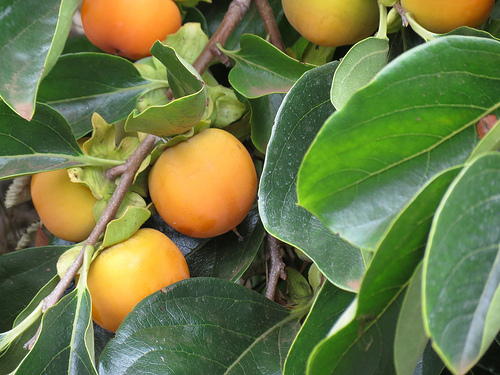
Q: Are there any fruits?
A: Yes, there is a fruit.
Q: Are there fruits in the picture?
A: Yes, there is a fruit.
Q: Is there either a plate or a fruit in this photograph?
A: Yes, there is a fruit.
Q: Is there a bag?
A: No, there are no bags.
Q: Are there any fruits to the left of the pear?
A: Yes, there is a fruit to the left of the pear.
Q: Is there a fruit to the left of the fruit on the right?
A: Yes, there is a fruit to the left of the pear.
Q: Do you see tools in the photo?
A: No, there are no tools.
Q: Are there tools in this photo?
A: No, there are no tools.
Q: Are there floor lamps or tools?
A: No, there are no tools or floor lamps.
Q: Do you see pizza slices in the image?
A: No, there are no pizza slices.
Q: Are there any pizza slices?
A: No, there are no pizza slices.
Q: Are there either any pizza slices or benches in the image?
A: No, there are no pizza slices or benches.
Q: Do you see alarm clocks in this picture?
A: No, there are no alarm clocks.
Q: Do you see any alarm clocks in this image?
A: No, there are no alarm clocks.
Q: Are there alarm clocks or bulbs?
A: No, there are no alarm clocks or bulbs.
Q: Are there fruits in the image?
A: Yes, there is a fruit.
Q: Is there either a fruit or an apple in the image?
A: Yes, there is a fruit.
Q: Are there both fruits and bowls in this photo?
A: No, there is a fruit but no bowls.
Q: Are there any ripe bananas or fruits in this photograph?
A: Yes, there is a ripe fruit.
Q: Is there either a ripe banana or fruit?
A: Yes, there is a ripe fruit.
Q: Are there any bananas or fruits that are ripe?
A: Yes, the fruit is ripe.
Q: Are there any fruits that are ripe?
A: Yes, there is a ripe fruit.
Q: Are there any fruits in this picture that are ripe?
A: Yes, there is a fruit that is ripe.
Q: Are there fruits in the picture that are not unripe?
A: Yes, there is an ripe fruit.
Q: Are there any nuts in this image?
A: No, there are no nuts.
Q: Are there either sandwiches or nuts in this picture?
A: No, there are no nuts or sandwiches.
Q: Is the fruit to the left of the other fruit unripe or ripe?
A: The fruit is ripe.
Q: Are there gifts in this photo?
A: No, there are no gifts.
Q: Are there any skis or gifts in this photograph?
A: No, there are no gifts or skis.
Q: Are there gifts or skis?
A: No, there are no gifts or skis.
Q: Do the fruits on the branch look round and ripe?
A: Yes, the fruits are round and ripe.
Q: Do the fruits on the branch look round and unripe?
A: No, the fruits are round but ripe.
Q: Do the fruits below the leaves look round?
A: Yes, the fruits are round.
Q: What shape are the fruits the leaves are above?
A: The fruits are round.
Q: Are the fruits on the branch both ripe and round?
A: Yes, the fruits are ripe and round.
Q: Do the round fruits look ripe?
A: Yes, the fruits are ripe.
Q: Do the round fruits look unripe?
A: No, the fruits are ripe.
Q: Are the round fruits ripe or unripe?
A: The fruits are ripe.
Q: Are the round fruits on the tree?
A: Yes, the fruits are on the tree.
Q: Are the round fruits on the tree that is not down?
A: Yes, the fruits are on the tree.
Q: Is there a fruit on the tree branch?
A: Yes, there are fruits on the branch.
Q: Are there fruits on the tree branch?
A: Yes, there are fruits on the branch.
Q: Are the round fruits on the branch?
A: Yes, the fruits are on the branch.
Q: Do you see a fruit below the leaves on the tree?
A: Yes, there are fruits below the leaves.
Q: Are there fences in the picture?
A: No, there are no fences.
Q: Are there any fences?
A: No, there are no fences.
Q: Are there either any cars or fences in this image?
A: No, there are no fences or cars.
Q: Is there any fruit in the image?
A: Yes, there is a fruit.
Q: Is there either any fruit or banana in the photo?
A: Yes, there is a fruit.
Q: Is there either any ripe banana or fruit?
A: Yes, there is a ripe fruit.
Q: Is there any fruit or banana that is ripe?
A: Yes, the fruit is ripe.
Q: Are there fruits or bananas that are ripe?
A: Yes, the fruit is ripe.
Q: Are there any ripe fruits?
A: Yes, there is a ripe fruit.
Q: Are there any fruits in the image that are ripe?
A: Yes, there is a fruit that is ripe.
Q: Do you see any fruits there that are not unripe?
A: Yes, there is an ripe fruit.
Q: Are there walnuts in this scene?
A: No, there are no walnuts.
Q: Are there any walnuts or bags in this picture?
A: No, there are no walnuts or bags.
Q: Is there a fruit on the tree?
A: Yes, there is a fruit on the tree.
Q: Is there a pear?
A: Yes, there is a pear.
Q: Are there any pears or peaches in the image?
A: Yes, there is a pear.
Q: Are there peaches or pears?
A: Yes, there is a pear.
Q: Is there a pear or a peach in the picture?
A: Yes, there is a pear.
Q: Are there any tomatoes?
A: No, there are no tomatoes.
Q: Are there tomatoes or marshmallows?
A: No, there are no tomatoes or marshmallows.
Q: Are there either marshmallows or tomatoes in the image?
A: No, there are no tomatoes or marshmallows.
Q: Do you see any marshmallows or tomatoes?
A: No, there are no tomatoes or marshmallows.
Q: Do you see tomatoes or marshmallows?
A: No, there are no tomatoes or marshmallows.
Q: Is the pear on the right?
A: Yes, the pear is on the right of the image.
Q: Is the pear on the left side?
A: No, the pear is on the right of the image.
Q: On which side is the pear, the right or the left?
A: The pear is on the right of the image.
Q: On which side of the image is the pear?
A: The pear is on the right of the image.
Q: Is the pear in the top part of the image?
A: Yes, the pear is in the top of the image.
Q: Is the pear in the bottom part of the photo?
A: No, the pear is in the top of the image.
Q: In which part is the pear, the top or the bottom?
A: The pear is in the top of the image.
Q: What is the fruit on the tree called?
A: The fruit is a pear.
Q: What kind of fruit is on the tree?
A: The fruit is a pear.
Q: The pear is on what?
A: The pear is on the tree.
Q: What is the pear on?
A: The pear is on the tree.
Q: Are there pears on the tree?
A: Yes, there is a pear on the tree.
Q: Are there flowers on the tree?
A: No, there is a pear on the tree.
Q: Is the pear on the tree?
A: Yes, the pear is on the tree.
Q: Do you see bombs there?
A: No, there are no bombs.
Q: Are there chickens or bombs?
A: No, there are no bombs or chickens.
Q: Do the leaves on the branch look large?
A: Yes, the leaves are large.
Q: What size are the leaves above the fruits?
A: The leaves are large.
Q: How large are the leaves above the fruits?
A: The leaves are large.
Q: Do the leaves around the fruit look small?
A: No, the leaves are large.